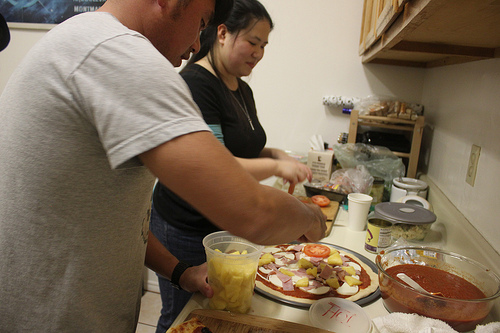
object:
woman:
[150, 0, 316, 329]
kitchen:
[4, 0, 499, 328]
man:
[0, 1, 326, 327]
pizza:
[248, 239, 383, 303]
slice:
[305, 244, 331, 257]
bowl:
[375, 245, 499, 324]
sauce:
[386, 264, 485, 297]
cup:
[347, 193, 373, 231]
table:
[170, 148, 499, 331]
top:
[153, 60, 269, 230]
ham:
[279, 274, 297, 291]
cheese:
[208, 246, 255, 309]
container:
[201, 231, 262, 314]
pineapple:
[209, 248, 253, 307]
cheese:
[266, 246, 365, 296]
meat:
[333, 270, 354, 281]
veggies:
[267, 235, 357, 298]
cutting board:
[292, 196, 340, 234]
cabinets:
[356, 1, 500, 67]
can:
[364, 216, 396, 254]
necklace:
[208, 53, 255, 131]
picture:
[1, 0, 102, 30]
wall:
[6, 1, 441, 288]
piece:
[295, 278, 309, 288]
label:
[378, 228, 392, 251]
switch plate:
[462, 142, 482, 186]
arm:
[89, 26, 328, 245]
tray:
[251, 234, 384, 309]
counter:
[168, 153, 500, 331]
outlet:
[465, 144, 481, 187]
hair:
[180, 0, 275, 140]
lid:
[308, 297, 373, 331]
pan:
[247, 236, 386, 307]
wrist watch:
[171, 261, 192, 285]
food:
[246, 241, 378, 306]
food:
[207, 248, 260, 315]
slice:
[312, 194, 330, 206]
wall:
[412, 57, 498, 274]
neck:
[191, 46, 237, 93]